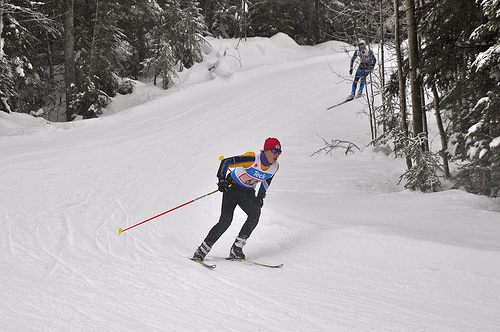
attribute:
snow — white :
[323, 185, 484, 318]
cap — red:
[255, 130, 291, 157]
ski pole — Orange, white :
[128, 191, 217, 222]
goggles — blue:
[260, 150, 279, 159]